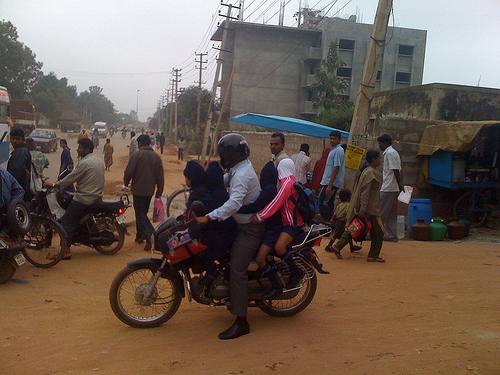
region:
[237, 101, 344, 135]
Blue awning over sidewalk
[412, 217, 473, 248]
Pots sitting on the road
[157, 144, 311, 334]
Family of four on motorcycle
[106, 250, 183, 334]
Front tire of motorcycle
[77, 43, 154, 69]
Hazy blue sky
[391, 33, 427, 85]
tattered worn buildings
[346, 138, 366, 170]
Yellow sign on pole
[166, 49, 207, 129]
Utility poles along the street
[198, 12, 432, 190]
A concrete block building.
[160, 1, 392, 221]
Wood electric poles along the road.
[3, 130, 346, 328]
People on motorcycles.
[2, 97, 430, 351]
People are walking on the streets.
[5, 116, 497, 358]
The streets are made of dirt.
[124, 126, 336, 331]
Four people ride the motorcycle in the middle.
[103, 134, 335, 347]
A man rides a motorcycle with three children.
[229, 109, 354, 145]
A blue umbrella near the building.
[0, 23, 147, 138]
Trees along the road.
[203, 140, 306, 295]
Four people riding on one motrocycle.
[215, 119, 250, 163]
The man is wearing a helmet.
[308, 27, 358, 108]
The building has windows.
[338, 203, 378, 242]
The person is carrying child backpack.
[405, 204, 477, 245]
Ceramic vases on the ground.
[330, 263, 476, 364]
The ground is dirt.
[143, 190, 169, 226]
The person is carrying a pink bag.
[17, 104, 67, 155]
Cars driving on the road.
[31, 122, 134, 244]
A man on the motorcycle.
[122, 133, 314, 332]
three people riding a motorcycle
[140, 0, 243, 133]
several wood electrical poles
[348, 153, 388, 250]
a woman carrying a red bag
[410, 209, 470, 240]
several vases on the ground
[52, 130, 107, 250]
a man sitting on a motorcycle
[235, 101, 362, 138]
a blue canopy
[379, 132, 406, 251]
person in small town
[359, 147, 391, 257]
person in small town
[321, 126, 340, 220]
person in small town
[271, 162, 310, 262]
person in small town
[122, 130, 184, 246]
person in small town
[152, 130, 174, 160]
person in small town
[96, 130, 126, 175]
person in small town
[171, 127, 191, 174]
person in small town